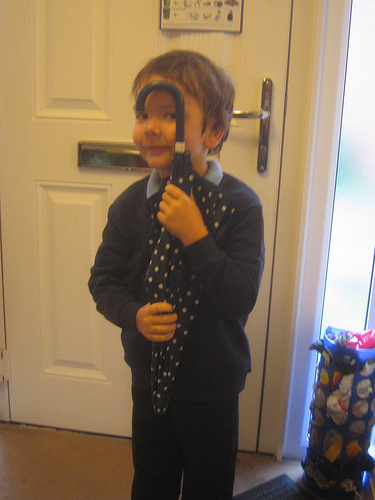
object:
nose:
[144, 118, 163, 136]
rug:
[230, 470, 310, 499]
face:
[132, 73, 207, 170]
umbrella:
[135, 79, 237, 416]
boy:
[88, 48, 265, 499]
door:
[0, 0, 294, 452]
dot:
[159, 282, 163, 289]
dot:
[189, 311, 198, 323]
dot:
[161, 268, 171, 280]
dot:
[154, 251, 167, 261]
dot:
[160, 255, 165, 261]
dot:
[178, 302, 188, 315]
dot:
[179, 303, 188, 315]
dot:
[171, 359, 181, 367]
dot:
[152, 374, 164, 387]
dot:
[209, 217, 222, 229]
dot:
[169, 243, 179, 256]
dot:
[154, 280, 164, 290]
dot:
[149, 287, 161, 301]